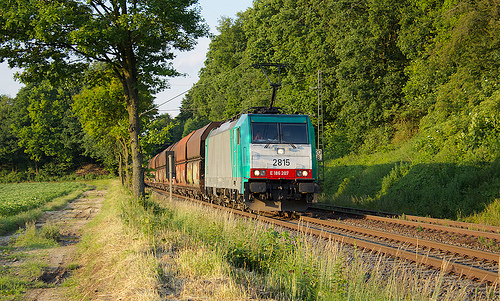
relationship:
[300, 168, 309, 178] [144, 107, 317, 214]
headlight on train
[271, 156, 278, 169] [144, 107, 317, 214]
number on train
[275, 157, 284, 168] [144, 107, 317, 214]
number on train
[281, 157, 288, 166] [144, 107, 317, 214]
number on train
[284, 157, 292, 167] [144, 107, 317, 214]
number on train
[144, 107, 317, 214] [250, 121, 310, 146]
train has windshield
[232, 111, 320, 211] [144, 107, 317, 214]
engine on train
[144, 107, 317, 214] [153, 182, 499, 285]
train on tracks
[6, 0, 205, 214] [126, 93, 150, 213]
tree has trunk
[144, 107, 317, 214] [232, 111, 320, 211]
train has engine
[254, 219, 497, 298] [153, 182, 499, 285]
gravel between tracks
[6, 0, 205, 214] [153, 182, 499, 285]
tree beside tracks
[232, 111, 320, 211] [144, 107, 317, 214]
engine in front of train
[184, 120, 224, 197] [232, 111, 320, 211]
car pulled by engine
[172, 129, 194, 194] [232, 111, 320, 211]
car pulled by engine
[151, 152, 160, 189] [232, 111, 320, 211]
car pulled by engine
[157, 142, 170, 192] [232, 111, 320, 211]
car pulled by engine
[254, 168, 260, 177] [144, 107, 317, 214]
headlight on train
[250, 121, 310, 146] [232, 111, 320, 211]
windshield on engine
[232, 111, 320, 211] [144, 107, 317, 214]
engine on front of train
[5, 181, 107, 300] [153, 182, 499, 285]
road next to tracks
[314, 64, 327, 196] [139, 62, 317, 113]
pole suspends wires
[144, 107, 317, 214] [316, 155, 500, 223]
train casts shadow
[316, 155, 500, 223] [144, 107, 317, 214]
shadow right of train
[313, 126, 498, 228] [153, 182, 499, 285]
grass next to tracks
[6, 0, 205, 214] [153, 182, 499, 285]
tree next to tracks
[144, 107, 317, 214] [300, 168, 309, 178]
train has headlight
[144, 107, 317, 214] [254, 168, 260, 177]
train has headlight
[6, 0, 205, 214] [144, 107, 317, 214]
tree next to train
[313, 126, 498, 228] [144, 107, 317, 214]
grass next to train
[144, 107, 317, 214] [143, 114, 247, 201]
train has side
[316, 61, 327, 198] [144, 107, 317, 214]
ladder tower next to train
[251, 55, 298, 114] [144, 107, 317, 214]
contraption on top of train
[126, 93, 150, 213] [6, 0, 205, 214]
trunk of tree